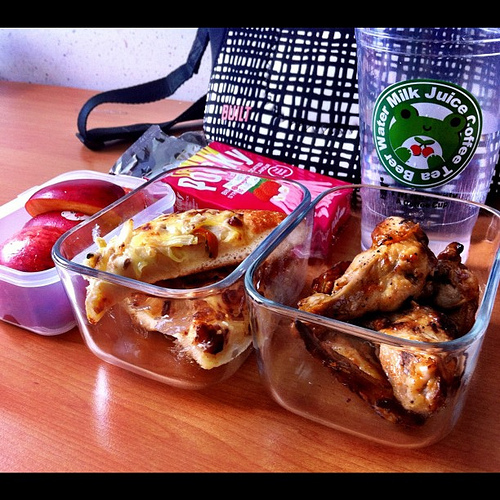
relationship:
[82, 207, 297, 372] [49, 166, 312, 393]
chicken inside container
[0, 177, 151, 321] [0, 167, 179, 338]
apple inside container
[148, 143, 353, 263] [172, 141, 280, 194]
box of pocky snacks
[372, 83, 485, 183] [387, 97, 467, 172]
icon has green animal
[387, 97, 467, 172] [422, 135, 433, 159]
green animal holding small fruit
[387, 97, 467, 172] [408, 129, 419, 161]
green animal holding small fruit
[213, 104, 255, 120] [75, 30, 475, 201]
"built" written on lunch bag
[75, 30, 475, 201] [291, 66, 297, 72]
lunch bag has white background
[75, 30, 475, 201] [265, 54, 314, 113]
lunch bag has crisscrossing lines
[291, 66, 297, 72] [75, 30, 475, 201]
white background on lunch bag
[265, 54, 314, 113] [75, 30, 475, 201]
crisscrossing lines on lunch bag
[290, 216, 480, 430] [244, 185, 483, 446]
chicken inside container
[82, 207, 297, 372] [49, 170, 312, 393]
chicken inside container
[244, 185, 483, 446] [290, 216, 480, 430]
container has chicken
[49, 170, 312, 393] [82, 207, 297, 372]
container has chicken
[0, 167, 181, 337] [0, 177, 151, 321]
container has apple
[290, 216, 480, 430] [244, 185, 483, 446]
chicken in container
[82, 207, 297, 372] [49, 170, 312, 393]
chicken in container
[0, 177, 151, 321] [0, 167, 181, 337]
apple in container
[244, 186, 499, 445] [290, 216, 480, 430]
container has chicken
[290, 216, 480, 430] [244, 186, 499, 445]
chicken in container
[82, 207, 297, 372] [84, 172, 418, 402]
chicken in containers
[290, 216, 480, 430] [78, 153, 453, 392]
chicken in containers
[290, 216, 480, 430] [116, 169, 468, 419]
chicken in containers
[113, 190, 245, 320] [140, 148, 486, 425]
chicken in containers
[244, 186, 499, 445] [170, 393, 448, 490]
container on table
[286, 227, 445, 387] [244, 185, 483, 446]
chicken in container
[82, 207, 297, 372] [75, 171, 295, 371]
chicken in container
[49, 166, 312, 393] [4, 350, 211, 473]
container on table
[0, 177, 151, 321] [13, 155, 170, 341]
apple in container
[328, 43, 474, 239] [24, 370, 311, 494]
cup on table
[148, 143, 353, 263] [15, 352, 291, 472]
box on table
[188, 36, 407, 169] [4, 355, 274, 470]
bag on table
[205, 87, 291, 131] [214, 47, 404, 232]
letters on bag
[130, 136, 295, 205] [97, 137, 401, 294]
sticks in box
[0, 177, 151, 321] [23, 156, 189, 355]
apple in container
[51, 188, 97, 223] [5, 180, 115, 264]
sticker on apple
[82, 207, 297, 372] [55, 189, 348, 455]
chicken in container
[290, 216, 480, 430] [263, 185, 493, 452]
chicken in container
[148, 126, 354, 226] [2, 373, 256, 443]
box on table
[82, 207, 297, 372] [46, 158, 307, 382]
chicken in container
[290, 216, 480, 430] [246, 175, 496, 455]
chicken in container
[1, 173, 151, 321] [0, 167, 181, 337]
apple in container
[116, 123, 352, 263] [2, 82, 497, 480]
satchet in table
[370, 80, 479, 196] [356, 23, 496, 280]
emblem on cup